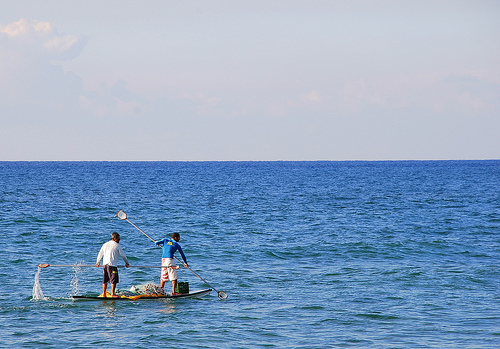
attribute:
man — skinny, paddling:
[157, 235, 189, 299]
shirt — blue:
[156, 238, 188, 261]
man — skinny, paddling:
[95, 232, 130, 299]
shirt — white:
[94, 241, 128, 270]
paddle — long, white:
[116, 206, 230, 302]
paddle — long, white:
[38, 254, 192, 274]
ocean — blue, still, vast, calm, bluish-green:
[1, 159, 499, 345]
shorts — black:
[99, 267, 119, 284]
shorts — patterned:
[158, 256, 178, 284]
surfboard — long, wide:
[76, 284, 213, 302]